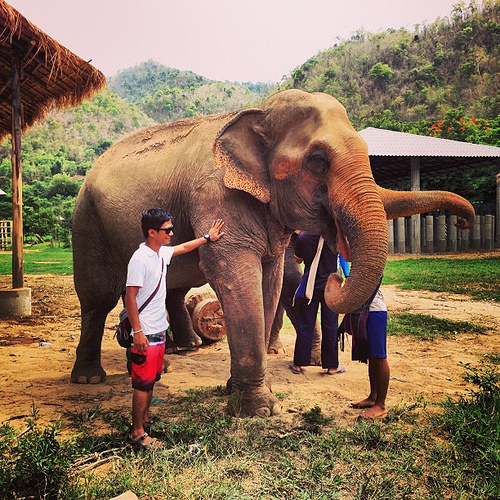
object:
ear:
[212, 108, 273, 205]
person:
[288, 230, 347, 375]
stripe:
[304, 235, 325, 305]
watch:
[204, 233, 211, 241]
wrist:
[199, 234, 210, 244]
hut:
[357, 126, 500, 256]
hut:
[0, 0, 107, 316]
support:
[426, 215, 434, 254]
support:
[447, 215, 458, 252]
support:
[411, 155, 421, 254]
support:
[0, 48, 32, 317]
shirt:
[124, 242, 175, 338]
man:
[123, 207, 225, 452]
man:
[334, 219, 389, 420]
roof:
[356, 126, 500, 157]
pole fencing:
[386, 213, 495, 254]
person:
[331, 217, 391, 419]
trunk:
[322, 171, 388, 315]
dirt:
[0, 274, 500, 500]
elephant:
[69, 89, 388, 418]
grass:
[0, 232, 500, 500]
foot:
[222, 373, 281, 419]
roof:
[0, 0, 109, 146]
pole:
[9, 69, 22, 288]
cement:
[0, 287, 32, 317]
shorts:
[366, 311, 387, 361]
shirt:
[367, 287, 388, 313]